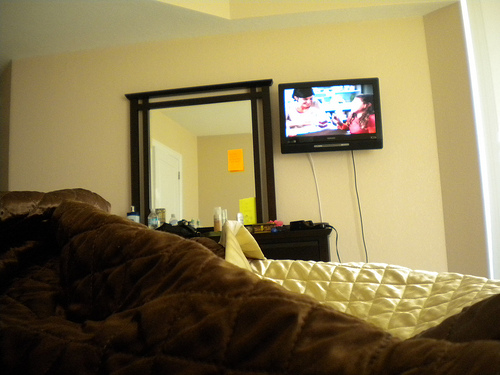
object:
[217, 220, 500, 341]
blanket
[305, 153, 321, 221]
cord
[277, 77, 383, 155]
television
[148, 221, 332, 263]
dresser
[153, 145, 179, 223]
door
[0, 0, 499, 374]
room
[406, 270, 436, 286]
white square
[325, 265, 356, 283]
white square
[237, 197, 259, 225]
stick note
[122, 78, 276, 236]
mirror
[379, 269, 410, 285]
square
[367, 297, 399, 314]
square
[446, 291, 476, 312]
square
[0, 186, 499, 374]
bedspread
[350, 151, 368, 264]
chord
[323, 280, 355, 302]
square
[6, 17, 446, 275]
wall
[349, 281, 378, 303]
white square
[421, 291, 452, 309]
square